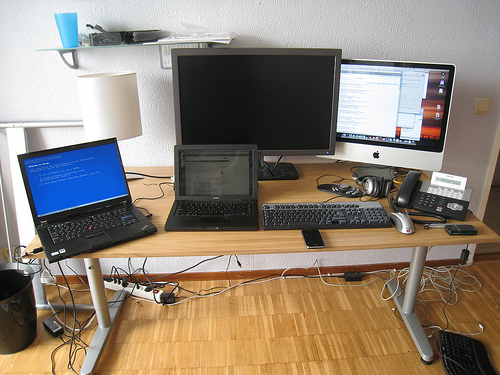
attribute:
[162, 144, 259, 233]
notebook — small, black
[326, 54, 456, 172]
computer — white, apple, mac, thunderbolt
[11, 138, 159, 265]
laptop — black, lenovo, thinkpad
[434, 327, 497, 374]
keyboard — black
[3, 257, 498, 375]
floor — wooden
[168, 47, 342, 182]
monitor — black, large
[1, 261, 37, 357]
basket — brown, black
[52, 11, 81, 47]
glass — blue, plastic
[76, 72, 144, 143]
lampshade — white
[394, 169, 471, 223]
phone — black, white, gray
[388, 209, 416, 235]
mouse — wireless, logitech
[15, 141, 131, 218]
screen — blue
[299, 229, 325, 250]
iphone — apple, cell phone